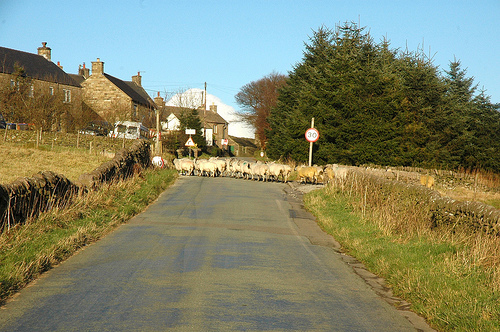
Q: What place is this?
A: It is a road.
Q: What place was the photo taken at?
A: It was taken at the road.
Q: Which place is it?
A: It is a road.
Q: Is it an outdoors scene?
A: Yes, it is outdoors.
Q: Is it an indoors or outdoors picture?
A: It is outdoors.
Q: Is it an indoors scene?
A: No, it is outdoors.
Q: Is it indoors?
A: No, it is outdoors.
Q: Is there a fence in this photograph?
A: Yes, there is a fence.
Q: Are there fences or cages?
A: Yes, there is a fence.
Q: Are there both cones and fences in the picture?
A: No, there is a fence but no cones.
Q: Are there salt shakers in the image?
A: No, there are no salt shakers.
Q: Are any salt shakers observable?
A: No, there are no salt shakers.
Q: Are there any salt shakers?
A: No, there are no salt shakers.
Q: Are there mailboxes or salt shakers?
A: No, there are no salt shakers or mailboxes.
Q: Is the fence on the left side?
A: Yes, the fence is on the left of the image.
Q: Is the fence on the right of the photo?
A: No, the fence is on the left of the image.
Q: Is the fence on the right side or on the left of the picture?
A: The fence is on the left of the image.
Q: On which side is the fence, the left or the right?
A: The fence is on the left of the image.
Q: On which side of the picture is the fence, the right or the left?
A: The fence is on the left of the image.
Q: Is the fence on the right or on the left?
A: The fence is on the left of the image.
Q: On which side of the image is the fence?
A: The fence is on the left of the image.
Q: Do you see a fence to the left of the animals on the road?
A: Yes, there is a fence to the left of the animals.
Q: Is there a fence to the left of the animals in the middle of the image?
A: Yes, there is a fence to the left of the animals.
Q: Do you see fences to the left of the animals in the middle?
A: Yes, there is a fence to the left of the animals.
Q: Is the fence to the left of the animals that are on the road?
A: Yes, the fence is to the left of the animals.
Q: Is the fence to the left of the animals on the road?
A: Yes, the fence is to the left of the animals.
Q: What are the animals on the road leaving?
A: The animals are leaving the field.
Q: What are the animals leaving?
A: The animals are leaving the field.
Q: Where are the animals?
A: The animals are on the road.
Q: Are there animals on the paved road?
A: Yes, there are animals on the road.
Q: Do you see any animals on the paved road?
A: Yes, there are animals on the road.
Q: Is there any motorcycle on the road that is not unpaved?
A: No, there are animals on the road.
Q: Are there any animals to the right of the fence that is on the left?
A: Yes, there are animals to the right of the fence.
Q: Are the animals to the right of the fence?
A: Yes, the animals are to the right of the fence.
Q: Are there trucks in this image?
A: No, there are no trucks.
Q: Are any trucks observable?
A: No, there are no trucks.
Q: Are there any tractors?
A: No, there are no tractors.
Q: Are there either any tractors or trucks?
A: No, there are no tractors or trucks.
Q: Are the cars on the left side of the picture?
A: Yes, the cars are on the left of the image.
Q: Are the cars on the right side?
A: No, the cars are on the left of the image.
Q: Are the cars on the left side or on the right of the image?
A: The cars are on the left of the image.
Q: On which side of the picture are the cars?
A: The cars are on the left of the image.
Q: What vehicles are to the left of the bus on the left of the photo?
A: The vehicles are cars.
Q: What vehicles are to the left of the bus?
A: The vehicles are cars.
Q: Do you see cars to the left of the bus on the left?
A: Yes, there are cars to the left of the bus.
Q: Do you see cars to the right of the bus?
A: No, the cars are to the left of the bus.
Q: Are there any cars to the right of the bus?
A: No, the cars are to the left of the bus.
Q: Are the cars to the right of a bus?
A: No, the cars are to the left of a bus.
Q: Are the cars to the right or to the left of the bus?
A: The cars are to the left of the bus.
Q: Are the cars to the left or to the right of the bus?
A: The cars are to the left of the bus.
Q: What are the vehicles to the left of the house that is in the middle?
A: The vehicles are cars.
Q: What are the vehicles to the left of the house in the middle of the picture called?
A: The vehicles are cars.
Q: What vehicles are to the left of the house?
A: The vehicles are cars.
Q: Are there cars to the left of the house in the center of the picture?
A: Yes, there are cars to the left of the house.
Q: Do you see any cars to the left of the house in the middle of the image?
A: Yes, there are cars to the left of the house.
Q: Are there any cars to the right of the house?
A: No, the cars are to the left of the house.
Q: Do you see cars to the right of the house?
A: No, the cars are to the left of the house.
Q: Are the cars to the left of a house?
A: Yes, the cars are to the left of a house.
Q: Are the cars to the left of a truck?
A: No, the cars are to the left of a house.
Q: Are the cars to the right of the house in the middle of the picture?
A: No, the cars are to the left of the house.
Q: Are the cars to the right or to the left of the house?
A: The cars are to the left of the house.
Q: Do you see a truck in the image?
A: No, there are no trucks.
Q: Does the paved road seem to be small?
A: Yes, the road is small.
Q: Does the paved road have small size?
A: Yes, the road is small.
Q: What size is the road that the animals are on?
A: The road is small.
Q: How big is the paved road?
A: The road is small.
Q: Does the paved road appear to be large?
A: No, the road is small.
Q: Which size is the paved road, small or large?
A: The road is small.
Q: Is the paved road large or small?
A: The road is small.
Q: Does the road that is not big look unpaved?
A: No, the road is paved.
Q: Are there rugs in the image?
A: No, there are no rugs.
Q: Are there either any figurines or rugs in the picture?
A: No, there are no rugs or figurines.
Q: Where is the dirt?
A: The dirt is on the road.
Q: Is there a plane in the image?
A: No, there are no airplanes.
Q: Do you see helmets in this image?
A: No, there are no helmets.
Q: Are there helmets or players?
A: No, there are no helmets or players.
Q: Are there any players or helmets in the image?
A: No, there are no helmets or players.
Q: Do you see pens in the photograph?
A: No, there are no pens.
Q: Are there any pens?
A: No, there are no pens.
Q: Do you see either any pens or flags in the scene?
A: No, there are no pens or flags.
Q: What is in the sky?
A: The clouds are in the sky.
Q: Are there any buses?
A: Yes, there is a bus.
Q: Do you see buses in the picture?
A: Yes, there is a bus.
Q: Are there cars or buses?
A: Yes, there is a bus.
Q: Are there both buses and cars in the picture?
A: Yes, there are both a bus and a car.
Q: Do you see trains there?
A: No, there are no trains.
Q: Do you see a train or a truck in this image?
A: No, there are no trains or trucks.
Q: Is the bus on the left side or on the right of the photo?
A: The bus is on the left of the image.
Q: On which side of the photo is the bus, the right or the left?
A: The bus is on the left of the image.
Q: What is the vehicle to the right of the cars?
A: The vehicle is a bus.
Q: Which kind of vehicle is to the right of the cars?
A: The vehicle is a bus.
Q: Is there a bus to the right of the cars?
A: Yes, there is a bus to the right of the cars.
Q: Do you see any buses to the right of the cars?
A: Yes, there is a bus to the right of the cars.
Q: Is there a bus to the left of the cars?
A: No, the bus is to the right of the cars.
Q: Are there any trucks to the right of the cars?
A: No, there is a bus to the right of the cars.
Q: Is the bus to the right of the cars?
A: Yes, the bus is to the right of the cars.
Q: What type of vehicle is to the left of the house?
A: The vehicle is a bus.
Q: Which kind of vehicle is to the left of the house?
A: The vehicle is a bus.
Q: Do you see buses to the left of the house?
A: Yes, there is a bus to the left of the house.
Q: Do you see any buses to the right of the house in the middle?
A: No, the bus is to the left of the house.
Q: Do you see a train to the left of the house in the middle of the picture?
A: No, there is a bus to the left of the house.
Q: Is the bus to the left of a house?
A: Yes, the bus is to the left of a house.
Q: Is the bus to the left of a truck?
A: No, the bus is to the left of a house.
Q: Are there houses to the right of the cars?
A: Yes, there is a house to the right of the cars.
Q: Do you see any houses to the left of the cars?
A: No, the house is to the right of the cars.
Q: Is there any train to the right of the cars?
A: No, there is a house to the right of the cars.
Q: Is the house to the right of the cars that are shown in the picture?
A: Yes, the house is to the right of the cars.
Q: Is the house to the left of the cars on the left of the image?
A: No, the house is to the right of the cars.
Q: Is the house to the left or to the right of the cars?
A: The house is to the right of the cars.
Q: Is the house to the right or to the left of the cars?
A: The house is to the right of the cars.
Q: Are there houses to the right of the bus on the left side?
A: Yes, there is a house to the right of the bus.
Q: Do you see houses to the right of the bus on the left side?
A: Yes, there is a house to the right of the bus.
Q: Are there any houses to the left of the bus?
A: No, the house is to the right of the bus.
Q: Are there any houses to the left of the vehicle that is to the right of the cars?
A: No, the house is to the right of the bus.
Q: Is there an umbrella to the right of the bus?
A: No, there is a house to the right of the bus.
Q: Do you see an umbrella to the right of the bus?
A: No, there is a house to the right of the bus.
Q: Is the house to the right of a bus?
A: Yes, the house is to the right of a bus.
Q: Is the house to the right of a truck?
A: No, the house is to the right of a bus.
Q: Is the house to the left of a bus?
A: No, the house is to the right of a bus.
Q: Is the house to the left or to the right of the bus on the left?
A: The house is to the right of the bus.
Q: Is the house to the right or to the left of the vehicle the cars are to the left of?
A: The house is to the right of the bus.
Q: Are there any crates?
A: No, there are no crates.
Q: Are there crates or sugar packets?
A: No, there are no crates or sugar packets.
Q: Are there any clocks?
A: No, there are no clocks.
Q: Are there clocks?
A: No, there are no clocks.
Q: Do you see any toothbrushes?
A: No, there are no toothbrushes.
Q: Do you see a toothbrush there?
A: No, there are no toothbrushes.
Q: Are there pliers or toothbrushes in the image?
A: No, there are no toothbrushes or pliers.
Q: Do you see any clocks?
A: No, there are no clocks.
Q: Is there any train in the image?
A: No, there are no trains.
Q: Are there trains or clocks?
A: No, there are no trains or clocks.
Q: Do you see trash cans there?
A: No, there are no trash cans.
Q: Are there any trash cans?
A: No, there are no trash cans.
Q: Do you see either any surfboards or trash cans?
A: No, there are no trash cans or surfboards.